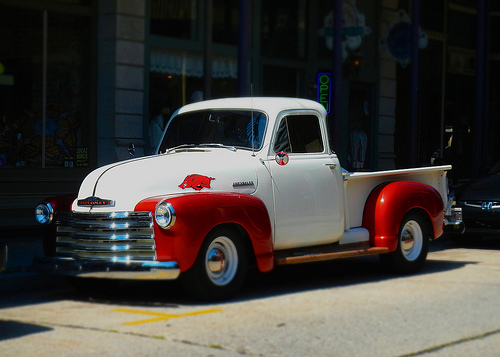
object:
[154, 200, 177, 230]
light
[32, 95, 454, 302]
truck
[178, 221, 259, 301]
tire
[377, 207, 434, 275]
tire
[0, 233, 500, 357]
pavement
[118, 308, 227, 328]
guidlines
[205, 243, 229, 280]
hubcaps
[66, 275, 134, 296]
tires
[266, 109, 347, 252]
door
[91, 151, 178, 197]
stripe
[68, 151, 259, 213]
hood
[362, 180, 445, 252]
metal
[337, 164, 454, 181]
edge